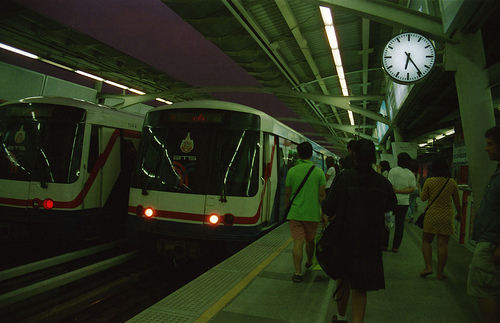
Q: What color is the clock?
A: White.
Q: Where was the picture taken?
A: In a subway.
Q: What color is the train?
A: White and red.